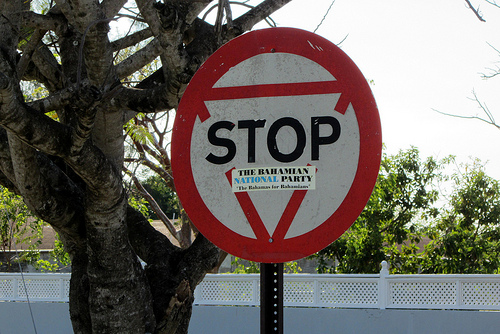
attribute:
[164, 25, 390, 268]
sign — round, white, black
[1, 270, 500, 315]
fence — long, white, wooden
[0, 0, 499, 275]
trees — leafy, green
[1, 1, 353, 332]
trunk — twisted, large, brown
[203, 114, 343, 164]
letters — black, dark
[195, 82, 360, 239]
triangle — red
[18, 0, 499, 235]
sky — grey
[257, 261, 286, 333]
post — metal, black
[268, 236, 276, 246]
bolt — silver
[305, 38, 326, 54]
scratch — white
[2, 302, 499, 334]
road — grey